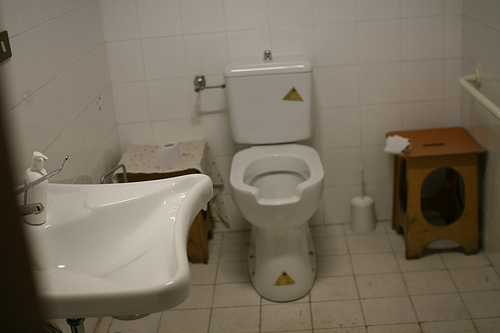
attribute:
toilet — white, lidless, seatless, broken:
[223, 54, 326, 304]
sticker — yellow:
[281, 88, 302, 103]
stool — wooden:
[385, 127, 489, 261]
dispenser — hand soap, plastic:
[23, 151, 49, 226]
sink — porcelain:
[14, 173, 215, 319]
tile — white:
[140, 34, 187, 81]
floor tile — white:
[353, 271, 410, 301]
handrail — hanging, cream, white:
[458, 67, 500, 120]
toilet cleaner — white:
[351, 165, 377, 236]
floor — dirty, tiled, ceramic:
[97, 220, 499, 333]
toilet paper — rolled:
[159, 140, 182, 171]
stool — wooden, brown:
[115, 142, 213, 265]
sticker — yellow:
[274, 272, 295, 287]